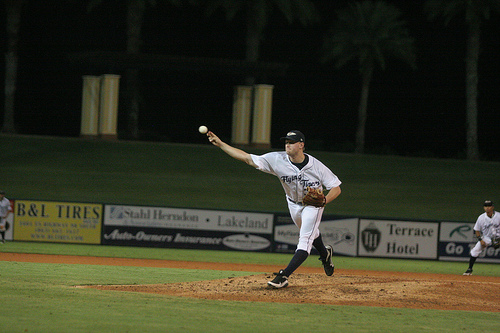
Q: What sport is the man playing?
A: Baseball.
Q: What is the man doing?
A: Pitching.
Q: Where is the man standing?
A: Pitcher's mound.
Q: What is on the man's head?
A: Baseball cap.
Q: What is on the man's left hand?
A: Catcher's mit.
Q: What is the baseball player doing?
A: Pitching the ball.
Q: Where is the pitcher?
A: On the mound.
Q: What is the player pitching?
A: The ball.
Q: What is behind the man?
A: A black and white sign.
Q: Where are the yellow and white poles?
A: By the trees.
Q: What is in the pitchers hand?
A: A glove.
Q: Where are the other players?
A: In their position.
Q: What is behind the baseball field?
A: Palm Trees.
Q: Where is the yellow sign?
A: Next to the black and white sign.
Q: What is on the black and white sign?
A: Advertisements.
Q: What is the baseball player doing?
A: Delivering a pitch.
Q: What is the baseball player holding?
A: A baseball glove.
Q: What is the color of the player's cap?
A: Black.